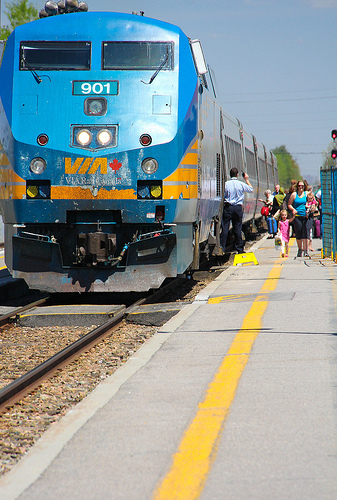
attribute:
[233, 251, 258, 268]
stool — yellow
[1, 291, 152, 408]
track — brown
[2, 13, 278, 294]
train — blue, yellow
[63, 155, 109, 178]
via — yellow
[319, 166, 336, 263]
fence — blue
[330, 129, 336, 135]
light — red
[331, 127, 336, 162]
lights — red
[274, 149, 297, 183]
tree — green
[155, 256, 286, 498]
line — yellow, straight, painted, yelllow